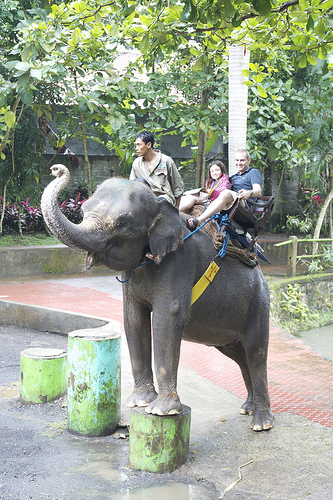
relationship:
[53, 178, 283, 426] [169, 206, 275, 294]
elephant has back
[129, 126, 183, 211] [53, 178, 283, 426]
man on elephant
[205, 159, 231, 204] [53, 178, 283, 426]
child on elephant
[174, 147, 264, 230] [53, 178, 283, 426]
father on elephant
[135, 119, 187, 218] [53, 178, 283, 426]
man driving elephant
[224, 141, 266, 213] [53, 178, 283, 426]
father riding elephant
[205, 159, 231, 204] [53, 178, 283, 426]
child riding elephant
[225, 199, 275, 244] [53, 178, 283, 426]
bench on elephant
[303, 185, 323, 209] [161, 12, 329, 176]
flower in tree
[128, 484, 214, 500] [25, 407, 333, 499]
puddle on ground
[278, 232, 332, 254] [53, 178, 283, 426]
rail behind elephant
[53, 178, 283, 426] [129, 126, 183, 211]
elephant carrying man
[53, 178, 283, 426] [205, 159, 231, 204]
elephant carrying child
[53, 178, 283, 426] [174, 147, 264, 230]
elephant carrying father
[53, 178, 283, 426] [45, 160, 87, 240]
elephant has trunk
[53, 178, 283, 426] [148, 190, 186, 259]
elephant has ear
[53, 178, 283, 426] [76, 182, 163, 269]
elephant has head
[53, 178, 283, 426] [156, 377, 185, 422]
elephant has foot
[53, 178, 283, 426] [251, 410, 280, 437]
elephant has foot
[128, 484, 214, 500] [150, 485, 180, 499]
puddle of mud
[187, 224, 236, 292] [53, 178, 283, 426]
harness on elephant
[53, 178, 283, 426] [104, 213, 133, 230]
elephant has eye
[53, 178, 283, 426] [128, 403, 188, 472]
elephant on block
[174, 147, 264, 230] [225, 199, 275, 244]
father in seat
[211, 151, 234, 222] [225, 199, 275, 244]
child in seat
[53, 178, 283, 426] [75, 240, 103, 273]
elephant has mouth